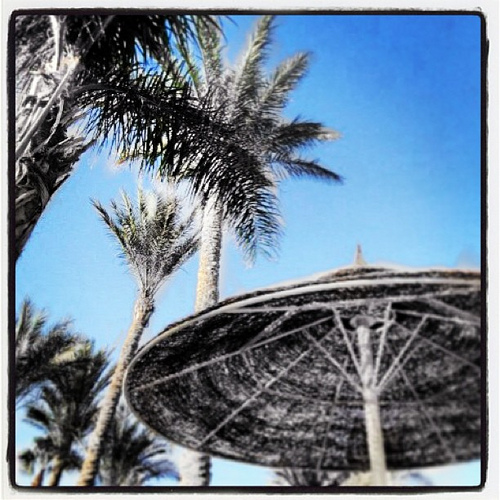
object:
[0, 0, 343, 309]
tree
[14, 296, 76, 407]
palm tree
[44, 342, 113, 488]
palm tree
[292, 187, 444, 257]
clouds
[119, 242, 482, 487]
umbrella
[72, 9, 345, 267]
leaves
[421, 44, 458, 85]
part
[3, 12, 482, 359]
sky